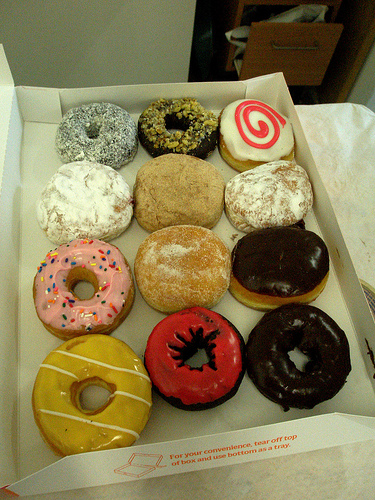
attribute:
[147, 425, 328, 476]
instructions — orange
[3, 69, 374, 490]
box — cardboard, white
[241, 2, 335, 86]
drawer — open, brown, wooden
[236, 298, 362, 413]
donut — chocolate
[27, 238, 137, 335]
donut — pink, frosted, strawberry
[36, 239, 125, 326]
sprinkles — rainbow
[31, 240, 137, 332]
frosting — pink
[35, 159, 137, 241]
donut — filled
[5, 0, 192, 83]
surface — white, clean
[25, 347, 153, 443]
lines — white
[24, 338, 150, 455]
donut — yellow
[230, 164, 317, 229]
powder — white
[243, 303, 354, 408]
frosting — chocolate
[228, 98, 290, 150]
swirl — pink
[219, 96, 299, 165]
donut — white, filled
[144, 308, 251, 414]
donut — chocolate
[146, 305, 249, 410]
frosting — red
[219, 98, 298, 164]
frosting — white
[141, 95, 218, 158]
donut — chocolate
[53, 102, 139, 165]
doughnut — chocolate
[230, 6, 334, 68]
bag — white, plastic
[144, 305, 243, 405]
cream — red